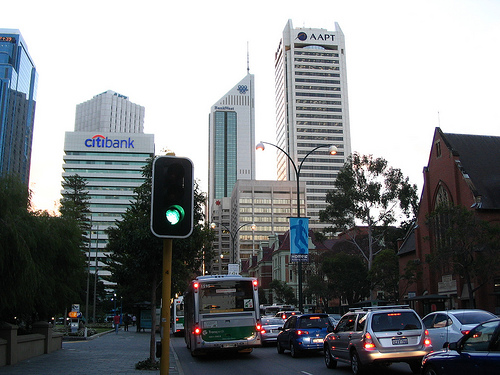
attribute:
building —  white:
[206, 41, 256, 226]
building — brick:
[397, 126, 499, 318]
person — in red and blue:
[112, 311, 120, 331]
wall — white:
[237, 107, 253, 174]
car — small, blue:
[271, 307, 341, 361]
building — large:
[281, 33, 363, 202]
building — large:
[217, 65, 264, 198]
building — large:
[0, 41, 40, 151]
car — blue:
[272, 311, 349, 353]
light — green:
[148, 155, 193, 239]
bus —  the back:
[179, 273, 264, 363]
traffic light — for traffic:
[149, 153, 195, 239]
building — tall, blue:
[0, 22, 42, 190]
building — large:
[232, 182, 307, 269]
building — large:
[275, 17, 355, 219]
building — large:
[207, 67, 258, 219]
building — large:
[60, 134, 152, 289]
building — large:
[65, 92, 158, 133]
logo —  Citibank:
[72, 133, 161, 158]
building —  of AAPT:
[271, 17, 357, 234]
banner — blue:
[284, 216, 311, 265]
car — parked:
[325, 301, 434, 371]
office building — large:
[54, 87, 161, 326]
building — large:
[0, 22, 35, 236]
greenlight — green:
[166, 206, 185, 227]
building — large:
[53, 82, 159, 339]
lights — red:
[190, 321, 270, 339]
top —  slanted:
[210, 72, 253, 102]